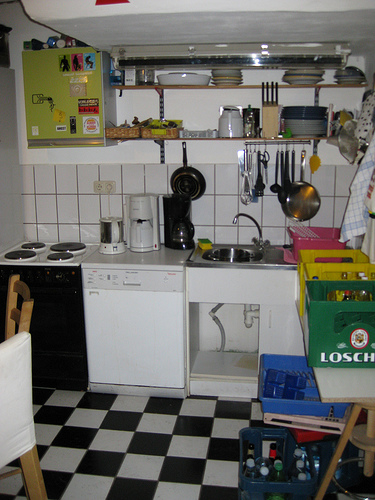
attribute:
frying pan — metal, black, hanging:
[170, 141, 206, 200]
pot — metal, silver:
[280, 150, 320, 221]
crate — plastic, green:
[303, 280, 374, 368]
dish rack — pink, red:
[286, 227, 349, 261]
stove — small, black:
[1, 241, 101, 392]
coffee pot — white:
[124, 193, 159, 251]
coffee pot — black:
[162, 193, 195, 250]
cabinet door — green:
[23, 46, 106, 149]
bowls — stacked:
[282, 68, 324, 85]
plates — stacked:
[280, 105, 327, 136]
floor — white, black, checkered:
[0, 385, 338, 499]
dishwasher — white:
[81, 244, 195, 399]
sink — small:
[202, 246, 264, 262]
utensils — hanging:
[241, 141, 294, 205]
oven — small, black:
[0, 287, 88, 390]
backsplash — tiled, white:
[21, 164, 360, 244]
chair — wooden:
[3, 274, 35, 340]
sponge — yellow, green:
[198, 238, 213, 250]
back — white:
[0, 331, 35, 470]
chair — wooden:
[0, 332, 48, 500]